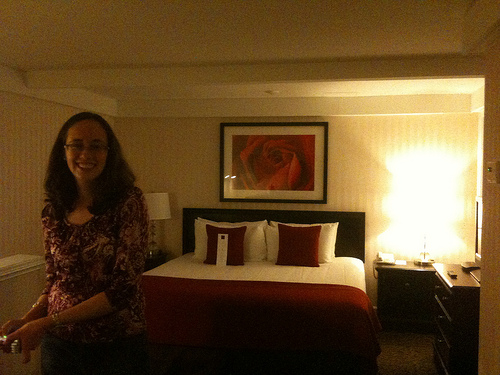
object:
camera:
[0, 334, 18, 357]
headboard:
[173, 202, 362, 263]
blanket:
[139, 263, 369, 370]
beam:
[24, 54, 487, 90]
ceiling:
[8, 4, 485, 121]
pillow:
[274, 222, 322, 268]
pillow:
[206, 227, 244, 267]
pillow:
[193, 214, 268, 264]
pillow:
[262, 218, 334, 267]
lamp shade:
[142, 189, 172, 223]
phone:
[377, 250, 395, 264]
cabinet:
[375, 265, 431, 329]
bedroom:
[1, 2, 491, 370]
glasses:
[66, 136, 111, 152]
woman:
[4, 114, 154, 375]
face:
[64, 120, 110, 183]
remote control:
[1, 330, 18, 354]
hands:
[4, 315, 52, 361]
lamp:
[142, 191, 173, 252]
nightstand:
[143, 246, 175, 272]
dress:
[35, 185, 153, 350]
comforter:
[135, 222, 377, 371]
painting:
[222, 124, 324, 199]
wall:
[150, 107, 420, 208]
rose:
[234, 135, 311, 192]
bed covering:
[135, 273, 380, 368]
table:
[141, 248, 174, 271]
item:
[2, 334, 22, 354]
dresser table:
[423, 256, 483, 372]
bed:
[139, 200, 380, 357]